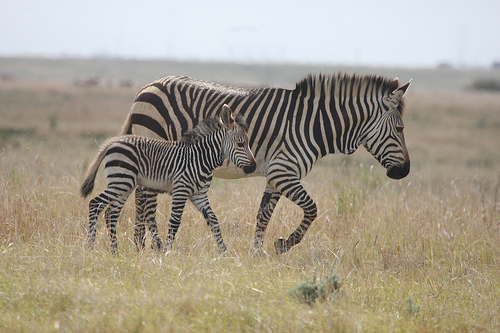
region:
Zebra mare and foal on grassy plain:
[78, 72, 414, 262]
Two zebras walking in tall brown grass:
[81, 70, 413, 254]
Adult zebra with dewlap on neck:
[118, 73, 411, 260]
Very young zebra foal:
[78, 100, 258, 260]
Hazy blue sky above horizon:
[0, 1, 499, 69]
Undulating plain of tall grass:
[3, 55, 499, 331]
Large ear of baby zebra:
[219, 100, 232, 124]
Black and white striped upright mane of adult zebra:
[296, 73, 398, 95]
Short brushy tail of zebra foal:
[80, 141, 111, 198]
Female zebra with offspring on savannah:
[79, 70, 412, 262]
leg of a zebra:
[279, 173, 329, 252]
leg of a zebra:
[242, 201, 287, 266]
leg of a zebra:
[198, 189, 240, 254]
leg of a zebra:
[170, 206, 191, 243]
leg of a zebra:
[141, 210, 163, 254]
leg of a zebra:
[130, 212, 157, 254]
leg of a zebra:
[102, 216, 144, 254]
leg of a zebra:
[67, 202, 108, 244]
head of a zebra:
[350, 60, 443, 187]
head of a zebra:
[195, 84, 279, 175]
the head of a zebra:
[358, 71, 411, 183]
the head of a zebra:
[218, 104, 258, 177]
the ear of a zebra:
[215, 99, 236, 129]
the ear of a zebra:
[388, 78, 413, 105]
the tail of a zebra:
[71, 138, 107, 202]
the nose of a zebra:
[246, 158, 261, 174]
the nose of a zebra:
[399, 155, 416, 180]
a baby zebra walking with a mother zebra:
[68, 61, 416, 271]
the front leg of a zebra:
[267, 159, 317, 259]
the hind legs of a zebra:
[81, 166, 135, 262]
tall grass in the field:
[11, 262, 176, 309]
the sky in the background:
[33, 6, 395, 32]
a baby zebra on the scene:
[71, 106, 253, 262]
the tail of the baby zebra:
[81, 143, 104, 194]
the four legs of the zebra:
[91, 181, 228, 253]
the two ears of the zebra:
[386, 77, 411, 101]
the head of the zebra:
[367, 80, 412, 179]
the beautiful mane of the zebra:
[300, 75, 390, 95]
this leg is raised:
[269, 160, 316, 251]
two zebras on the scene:
[64, 58, 411, 259]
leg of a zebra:
[254, 178, 277, 235]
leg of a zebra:
[205, 223, 240, 256]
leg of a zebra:
[150, 215, 176, 244]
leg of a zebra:
[76, 205, 111, 232]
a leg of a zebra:
[290, 205, 340, 241]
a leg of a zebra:
[240, 183, 293, 241]